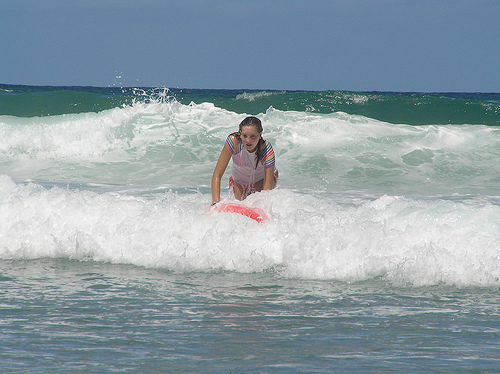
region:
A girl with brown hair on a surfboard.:
[209, 117, 279, 206]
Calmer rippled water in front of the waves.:
[2, 257, 496, 372]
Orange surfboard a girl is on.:
[210, 199, 270, 224]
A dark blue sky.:
[1, 1, 498, 92]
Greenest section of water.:
[2, 84, 497, 122]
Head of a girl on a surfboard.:
[239, 116, 262, 152]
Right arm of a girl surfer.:
[212, 137, 234, 204]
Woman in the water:
[206, 106, 295, 258]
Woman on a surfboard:
[198, 114, 287, 246]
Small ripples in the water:
[23, 300, 62, 348]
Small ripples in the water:
[58, 309, 98, 368]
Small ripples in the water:
[208, 284, 255, 337]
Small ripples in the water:
[337, 288, 394, 345]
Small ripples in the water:
[404, 294, 450, 346]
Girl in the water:
[205, 102, 322, 241]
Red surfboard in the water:
[205, 192, 299, 235]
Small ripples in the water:
[11, 316, 45, 363]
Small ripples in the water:
[98, 309, 156, 369]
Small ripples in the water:
[153, 305, 189, 350]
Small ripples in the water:
[201, 312, 260, 363]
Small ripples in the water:
[253, 311, 292, 353]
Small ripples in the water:
[298, 309, 353, 362]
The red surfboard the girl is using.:
[216, 202, 265, 224]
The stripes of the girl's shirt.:
[225, 134, 275, 166]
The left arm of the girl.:
[212, 140, 231, 202]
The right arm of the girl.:
[265, 167, 272, 188]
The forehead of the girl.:
[241, 124, 256, 133]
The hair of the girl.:
[232, 119, 265, 166]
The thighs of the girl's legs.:
[230, 179, 267, 204]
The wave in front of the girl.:
[5, 179, 498, 298]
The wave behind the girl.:
[0, 102, 497, 222]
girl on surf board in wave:
[196, 105, 304, 242]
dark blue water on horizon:
[8, 75, 418, 105]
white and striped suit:
[225, 142, 279, 188]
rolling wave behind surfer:
[27, 100, 444, 168]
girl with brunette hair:
[239, 113, 268, 157]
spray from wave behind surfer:
[112, 73, 199, 151]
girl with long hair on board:
[207, 105, 279, 219]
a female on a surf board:
[208, 109, 293, 239]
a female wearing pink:
[206, 116, 284, 237]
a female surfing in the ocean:
[182, 108, 284, 233]